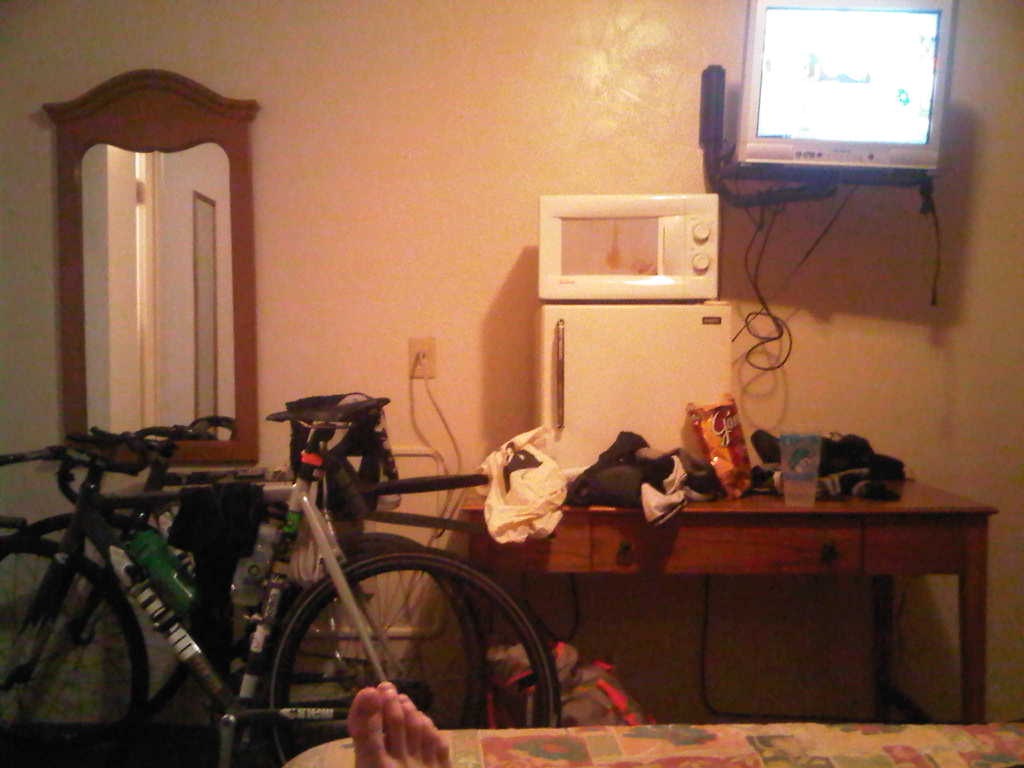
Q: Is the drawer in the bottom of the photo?
A: Yes, the drawer is in the bottom of the image.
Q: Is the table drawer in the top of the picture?
A: No, the drawer is in the bottom of the image.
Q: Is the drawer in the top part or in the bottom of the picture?
A: The drawer is in the bottom of the image.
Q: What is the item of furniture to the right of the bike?
A: The piece of furniture is a drawer.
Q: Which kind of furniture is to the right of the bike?
A: The piece of furniture is a drawer.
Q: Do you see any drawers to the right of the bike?
A: Yes, there is a drawer to the right of the bike.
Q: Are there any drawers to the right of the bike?
A: Yes, there is a drawer to the right of the bike.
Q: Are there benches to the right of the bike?
A: No, there is a drawer to the right of the bike.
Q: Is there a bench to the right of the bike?
A: No, there is a drawer to the right of the bike.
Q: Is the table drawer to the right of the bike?
A: Yes, the drawer is to the right of the bike.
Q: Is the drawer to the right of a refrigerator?
A: No, the drawer is to the right of the bike.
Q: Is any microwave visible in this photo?
A: Yes, there is a microwave.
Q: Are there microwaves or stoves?
A: Yes, there is a microwave.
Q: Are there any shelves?
A: No, there are no shelves.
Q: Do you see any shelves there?
A: No, there are no shelves.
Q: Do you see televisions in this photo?
A: Yes, there is a television.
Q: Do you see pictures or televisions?
A: Yes, there is a television.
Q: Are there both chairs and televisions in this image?
A: No, there is a television but no chairs.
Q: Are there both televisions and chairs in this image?
A: No, there is a television but no chairs.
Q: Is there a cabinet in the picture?
A: No, there are no cabinets.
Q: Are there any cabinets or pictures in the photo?
A: No, there are no cabinets or pictures.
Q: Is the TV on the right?
A: Yes, the TV is on the right of the image.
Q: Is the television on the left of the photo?
A: No, the television is on the right of the image.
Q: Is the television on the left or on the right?
A: The television is on the right of the image.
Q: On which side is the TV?
A: The TV is on the right of the image.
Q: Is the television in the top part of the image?
A: Yes, the television is in the top of the image.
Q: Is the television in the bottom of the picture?
A: No, the television is in the top of the image.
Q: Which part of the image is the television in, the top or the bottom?
A: The television is in the top of the image.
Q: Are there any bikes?
A: Yes, there is a bike.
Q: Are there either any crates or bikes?
A: Yes, there is a bike.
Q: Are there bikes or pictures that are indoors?
A: Yes, the bike is indoors.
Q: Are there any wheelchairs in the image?
A: No, there are no wheelchairs.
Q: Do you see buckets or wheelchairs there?
A: No, there are no wheelchairs or buckets.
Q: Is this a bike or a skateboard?
A: This is a bike.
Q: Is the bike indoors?
A: Yes, the bike is indoors.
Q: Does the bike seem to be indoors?
A: Yes, the bike is indoors.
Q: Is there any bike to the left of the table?
A: Yes, there is a bike to the left of the table.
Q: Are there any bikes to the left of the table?
A: Yes, there is a bike to the left of the table.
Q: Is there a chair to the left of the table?
A: No, there is a bike to the left of the table.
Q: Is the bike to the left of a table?
A: Yes, the bike is to the left of a table.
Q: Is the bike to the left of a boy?
A: No, the bike is to the left of a table.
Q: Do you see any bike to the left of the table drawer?
A: Yes, there is a bike to the left of the drawer.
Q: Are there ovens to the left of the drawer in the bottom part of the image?
A: No, there is a bike to the left of the drawer.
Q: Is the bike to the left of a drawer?
A: Yes, the bike is to the left of a drawer.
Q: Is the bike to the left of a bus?
A: No, the bike is to the left of a drawer.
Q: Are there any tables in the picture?
A: Yes, there is a table.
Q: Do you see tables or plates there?
A: Yes, there is a table.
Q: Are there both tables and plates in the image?
A: No, there is a table but no plates.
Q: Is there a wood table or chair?
A: Yes, there is a wood table.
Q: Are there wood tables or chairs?
A: Yes, there is a wood table.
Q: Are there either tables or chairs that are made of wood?
A: Yes, the table is made of wood.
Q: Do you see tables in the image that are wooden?
A: Yes, there is a wood table.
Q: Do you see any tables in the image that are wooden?
A: Yes, there is a table that is wooden.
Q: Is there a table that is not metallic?
A: Yes, there is a wooden table.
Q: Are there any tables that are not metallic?
A: Yes, there is a wooden table.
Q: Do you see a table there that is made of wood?
A: Yes, there is a table that is made of wood.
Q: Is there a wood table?
A: Yes, there is a table that is made of wood.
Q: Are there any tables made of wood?
A: Yes, there is a table that is made of wood.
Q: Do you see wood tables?
A: Yes, there is a table that is made of wood.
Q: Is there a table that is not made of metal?
A: Yes, there is a table that is made of wood.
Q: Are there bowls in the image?
A: No, there are no bowls.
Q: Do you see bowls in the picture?
A: No, there are no bowls.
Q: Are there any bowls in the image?
A: No, there are no bowls.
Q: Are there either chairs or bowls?
A: No, there are no bowls or chairs.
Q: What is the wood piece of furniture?
A: The piece of furniture is a table.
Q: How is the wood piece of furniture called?
A: The piece of furniture is a table.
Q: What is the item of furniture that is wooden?
A: The piece of furniture is a table.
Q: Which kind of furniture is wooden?
A: The furniture is a table.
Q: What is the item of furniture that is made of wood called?
A: The piece of furniture is a table.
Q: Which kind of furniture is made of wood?
A: The furniture is a table.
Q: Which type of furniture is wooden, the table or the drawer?
A: The table is wooden.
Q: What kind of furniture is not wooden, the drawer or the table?
A: The drawer is not wooden.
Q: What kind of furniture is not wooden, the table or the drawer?
A: The drawer is not wooden.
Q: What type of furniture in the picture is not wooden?
A: The furniture is a drawer.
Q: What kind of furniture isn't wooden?
A: The furniture is a drawer.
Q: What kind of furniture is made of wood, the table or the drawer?
A: The table is made of wood.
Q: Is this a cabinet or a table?
A: This is a table.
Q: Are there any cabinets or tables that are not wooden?
A: No, there is a table but it is wooden.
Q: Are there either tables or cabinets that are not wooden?
A: No, there is a table but it is wooden.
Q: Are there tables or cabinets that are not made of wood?
A: No, there is a table but it is made of wood.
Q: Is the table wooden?
A: Yes, the table is wooden.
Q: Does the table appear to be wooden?
A: Yes, the table is wooden.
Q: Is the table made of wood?
A: Yes, the table is made of wood.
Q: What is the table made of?
A: The table is made of wood.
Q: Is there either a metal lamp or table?
A: No, there is a table but it is wooden.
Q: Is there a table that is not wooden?
A: No, there is a table but it is wooden.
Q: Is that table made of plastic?
A: No, the table is made of wood.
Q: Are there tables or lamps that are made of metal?
A: No, there is a table but it is made of wood.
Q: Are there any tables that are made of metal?
A: No, there is a table but it is made of wood.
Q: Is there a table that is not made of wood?
A: No, there is a table but it is made of wood.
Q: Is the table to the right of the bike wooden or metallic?
A: The table is wooden.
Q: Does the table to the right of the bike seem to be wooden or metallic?
A: The table is wooden.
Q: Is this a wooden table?
A: Yes, this is a wooden table.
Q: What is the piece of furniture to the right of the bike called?
A: The piece of furniture is a table.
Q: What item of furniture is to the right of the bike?
A: The piece of furniture is a table.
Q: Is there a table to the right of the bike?
A: Yes, there is a table to the right of the bike.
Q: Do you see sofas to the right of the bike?
A: No, there is a table to the right of the bike.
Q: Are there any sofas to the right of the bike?
A: No, there is a table to the right of the bike.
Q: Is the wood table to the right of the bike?
A: Yes, the table is to the right of the bike.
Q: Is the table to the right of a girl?
A: No, the table is to the right of the bike.